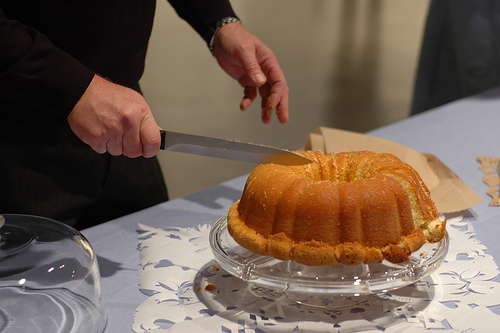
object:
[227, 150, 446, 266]
cake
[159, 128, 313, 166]
knife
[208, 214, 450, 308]
glass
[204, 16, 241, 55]
watch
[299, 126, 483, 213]
napkin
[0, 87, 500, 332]
table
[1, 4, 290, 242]
man